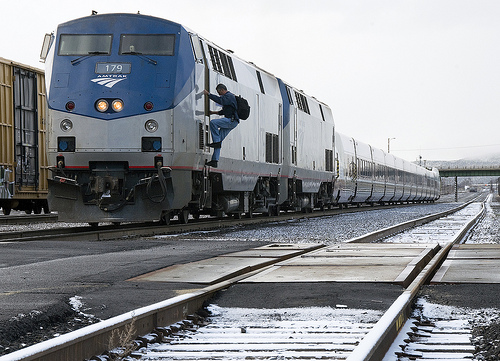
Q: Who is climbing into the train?
A: The man.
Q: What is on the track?
A: A train.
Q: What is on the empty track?
A: Snow.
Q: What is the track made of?
A: Iron.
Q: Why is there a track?
A: For the train to travel.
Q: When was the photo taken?
A: Daytime.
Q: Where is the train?
A: On the track.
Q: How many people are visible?
A: One.